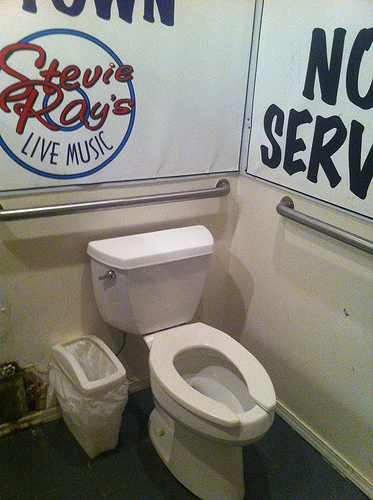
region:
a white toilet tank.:
[79, 209, 232, 335]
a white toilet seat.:
[147, 318, 274, 428]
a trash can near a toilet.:
[44, 317, 130, 461]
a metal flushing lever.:
[96, 260, 121, 296]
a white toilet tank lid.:
[85, 219, 213, 277]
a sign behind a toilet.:
[0, 23, 138, 180]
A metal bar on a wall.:
[0, 173, 242, 229]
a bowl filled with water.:
[188, 364, 249, 414]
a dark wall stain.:
[339, 294, 355, 328]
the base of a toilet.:
[143, 403, 255, 498]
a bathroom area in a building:
[8, 190, 315, 458]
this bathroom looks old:
[4, 332, 305, 495]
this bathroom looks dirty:
[5, 301, 231, 483]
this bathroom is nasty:
[82, 239, 288, 493]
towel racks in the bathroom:
[10, 186, 361, 266]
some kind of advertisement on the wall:
[4, 6, 206, 178]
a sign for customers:
[251, 20, 369, 187]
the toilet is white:
[93, 239, 271, 421]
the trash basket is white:
[45, 335, 131, 462]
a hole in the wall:
[2, 357, 58, 449]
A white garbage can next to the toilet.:
[39, 338, 140, 464]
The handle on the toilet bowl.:
[91, 264, 124, 285]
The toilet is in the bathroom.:
[145, 340, 279, 498]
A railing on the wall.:
[275, 194, 368, 248]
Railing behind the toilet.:
[5, 184, 237, 207]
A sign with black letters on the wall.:
[283, 39, 360, 157]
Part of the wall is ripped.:
[6, 348, 58, 413]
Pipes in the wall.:
[2, 359, 37, 417]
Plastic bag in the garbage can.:
[48, 372, 119, 423]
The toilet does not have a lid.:
[143, 309, 271, 428]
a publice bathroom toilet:
[53, 155, 353, 499]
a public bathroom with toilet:
[7, 162, 370, 498]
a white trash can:
[16, 306, 155, 480]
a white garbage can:
[22, 320, 178, 496]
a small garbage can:
[49, 327, 136, 457]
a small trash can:
[37, 329, 143, 487]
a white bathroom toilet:
[57, 225, 343, 498]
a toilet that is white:
[82, 211, 320, 498]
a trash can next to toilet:
[5, 211, 317, 485]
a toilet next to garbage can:
[25, 229, 338, 498]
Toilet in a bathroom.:
[71, 225, 297, 497]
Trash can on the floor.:
[25, 317, 162, 491]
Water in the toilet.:
[162, 324, 290, 443]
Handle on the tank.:
[101, 256, 136, 292]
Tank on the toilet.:
[67, 199, 260, 300]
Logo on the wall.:
[3, 22, 181, 197]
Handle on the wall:
[152, 163, 353, 263]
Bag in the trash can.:
[45, 335, 124, 436]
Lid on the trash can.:
[32, 331, 130, 400]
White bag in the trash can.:
[46, 346, 168, 431]